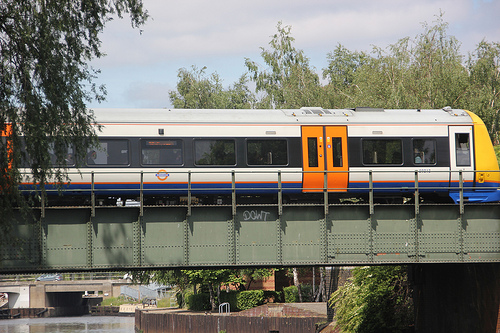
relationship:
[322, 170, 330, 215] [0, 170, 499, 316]
rail post on bridge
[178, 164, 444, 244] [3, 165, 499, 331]
rail post on bridge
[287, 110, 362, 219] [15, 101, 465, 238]
doors on train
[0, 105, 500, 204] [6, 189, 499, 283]
passenger train on bridge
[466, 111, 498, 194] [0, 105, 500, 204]
end of passenger train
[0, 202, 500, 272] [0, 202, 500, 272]
bridge on bridge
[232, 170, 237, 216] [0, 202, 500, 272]
post on bridge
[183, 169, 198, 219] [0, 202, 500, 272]
rail post on bridge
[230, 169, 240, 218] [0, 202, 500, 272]
post on bridge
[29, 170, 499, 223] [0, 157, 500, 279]
safety rail on bridge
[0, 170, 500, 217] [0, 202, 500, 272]
safety rail on bridge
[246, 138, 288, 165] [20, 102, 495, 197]
window on train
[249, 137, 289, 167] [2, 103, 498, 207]
window on train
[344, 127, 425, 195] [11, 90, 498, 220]
window on train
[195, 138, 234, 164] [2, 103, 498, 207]
window on train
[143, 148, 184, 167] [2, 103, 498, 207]
window on train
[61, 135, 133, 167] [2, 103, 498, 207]
window on train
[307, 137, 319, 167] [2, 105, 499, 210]
window on passenger train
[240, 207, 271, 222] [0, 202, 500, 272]
graffiti on bridge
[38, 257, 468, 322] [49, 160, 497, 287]
water under bridge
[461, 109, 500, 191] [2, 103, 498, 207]
end on train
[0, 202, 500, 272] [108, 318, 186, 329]
bridge over river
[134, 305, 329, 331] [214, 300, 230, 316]
river embankment with ladder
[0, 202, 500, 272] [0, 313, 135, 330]
bridge over river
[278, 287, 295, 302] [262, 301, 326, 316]
shubberies with path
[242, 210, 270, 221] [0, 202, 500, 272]
graffiti sprayed on bridge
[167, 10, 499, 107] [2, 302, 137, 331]
tree on side of river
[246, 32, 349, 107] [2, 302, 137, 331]
tree on side of river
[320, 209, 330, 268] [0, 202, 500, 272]
steel riveted onto bridge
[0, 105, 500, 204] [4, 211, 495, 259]
passenger train on bridge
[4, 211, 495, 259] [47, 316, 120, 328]
bridge over river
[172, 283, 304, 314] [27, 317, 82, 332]
bushes near river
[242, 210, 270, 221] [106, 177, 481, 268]
graffiti on bridge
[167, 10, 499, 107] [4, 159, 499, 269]
tree near bridge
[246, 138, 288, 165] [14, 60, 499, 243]
window on train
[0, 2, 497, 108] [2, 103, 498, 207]
sky above train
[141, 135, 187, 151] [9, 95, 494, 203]
electric display on train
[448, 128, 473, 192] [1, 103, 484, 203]
window built into passenger train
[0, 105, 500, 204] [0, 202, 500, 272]
passenger train riding on bridge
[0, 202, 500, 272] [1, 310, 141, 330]
bridge spanning over river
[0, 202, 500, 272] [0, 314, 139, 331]
bridge spanning over water